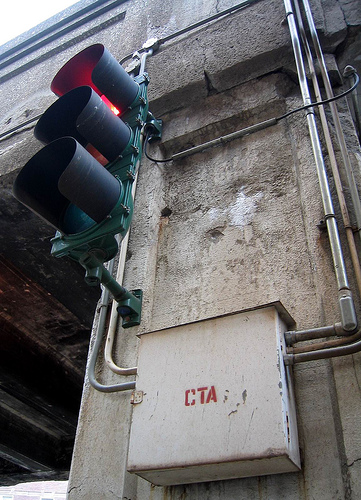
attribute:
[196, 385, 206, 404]
t —   letter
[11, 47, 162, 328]
traffic sign — is green, is black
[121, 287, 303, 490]
electrical box —  for electrical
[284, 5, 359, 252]
wire —  electric, with metal tubing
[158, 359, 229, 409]
cta —  wire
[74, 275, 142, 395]
tubing —  metal,  electric wire's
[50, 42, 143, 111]
traffic light —  red.,  for traffic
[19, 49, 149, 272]
light —  for traffic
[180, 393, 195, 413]
letter —   red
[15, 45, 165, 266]
signal —  green,  three way stop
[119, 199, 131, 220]
bolt — side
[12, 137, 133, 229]
signal — go  stop,  green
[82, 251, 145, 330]
support — green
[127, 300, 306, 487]
fuse box — metal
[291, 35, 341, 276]
rods — long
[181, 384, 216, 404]
cta —  red 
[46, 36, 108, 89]
light —  red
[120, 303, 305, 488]
box —  white,   labeled CTA